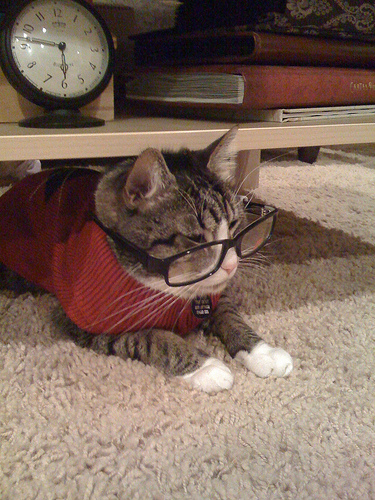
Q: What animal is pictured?
A: A house cat.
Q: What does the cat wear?
A: A red sweater and glasses.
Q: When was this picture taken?
A: 5:47.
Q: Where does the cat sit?
A: On beige carpet.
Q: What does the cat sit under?
A: A table.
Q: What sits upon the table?
A: Books.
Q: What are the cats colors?
A: Gray with white markings.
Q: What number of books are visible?
A: Four.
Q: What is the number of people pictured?
A: Zero.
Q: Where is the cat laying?
A: On the carpet.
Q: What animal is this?
A: Cat.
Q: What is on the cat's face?
A: Glasses.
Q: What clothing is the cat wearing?
A: Sweater.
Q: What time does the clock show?
A: 5:47.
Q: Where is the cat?
A: Under a shelf.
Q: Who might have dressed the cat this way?
A: Owner.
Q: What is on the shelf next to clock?
A: Photo albums.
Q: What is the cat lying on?
A: Carpet.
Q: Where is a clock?
A: Shelf over cat.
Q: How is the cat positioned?
A: Laying down.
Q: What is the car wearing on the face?
A: Glasses.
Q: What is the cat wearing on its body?
A: A sweater.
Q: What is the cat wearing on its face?
A: Glasses.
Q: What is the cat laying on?
A: A rug.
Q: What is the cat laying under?
A: A table.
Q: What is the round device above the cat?
A: A clock.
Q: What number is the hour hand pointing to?
A: 6.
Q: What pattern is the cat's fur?
A: Striped.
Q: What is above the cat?
A: A table.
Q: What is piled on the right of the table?
A: Books.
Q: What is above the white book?
A: A red book.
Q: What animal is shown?
A: Cat.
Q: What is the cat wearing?
A: Glasses.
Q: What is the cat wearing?
A: A sweater.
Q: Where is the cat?
A: Under a shelf.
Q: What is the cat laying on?
A: Carpet.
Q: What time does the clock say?
A: 5:46.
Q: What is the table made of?
A: Wood.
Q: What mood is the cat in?
A: Somber.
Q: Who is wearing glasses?
A: The cat.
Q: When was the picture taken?
A: 5:47.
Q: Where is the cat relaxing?
A: Under the shelf.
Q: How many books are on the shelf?
A: 3.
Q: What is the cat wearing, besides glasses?
A: Red cat sweater.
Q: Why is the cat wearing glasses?
A: To make a humorous photo.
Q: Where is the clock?
A: On the left side of the shelf.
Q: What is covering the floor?
A: Carpet.